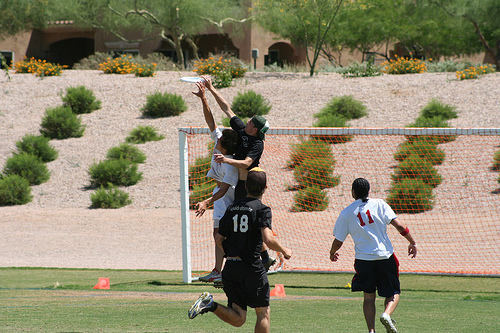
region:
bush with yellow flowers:
[17, 54, 39, 75]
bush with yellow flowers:
[43, 62, 65, 78]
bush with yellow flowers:
[101, 43, 133, 85]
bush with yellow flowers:
[136, 61, 161, 80]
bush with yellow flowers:
[187, 52, 228, 79]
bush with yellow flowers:
[388, 44, 420, 83]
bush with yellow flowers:
[456, 53, 495, 90]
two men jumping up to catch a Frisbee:
[171, 50, 273, 187]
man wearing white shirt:
[339, 195, 412, 258]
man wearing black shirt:
[215, 194, 278, 258]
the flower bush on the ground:
[7, 56, 67, 78]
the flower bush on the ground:
[98, 50, 155, 77]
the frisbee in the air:
[180, 73, 204, 82]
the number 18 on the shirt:
[232, 213, 247, 233]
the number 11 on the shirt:
[355, 209, 375, 225]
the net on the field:
[178, 127, 498, 283]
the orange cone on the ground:
[92, 275, 109, 288]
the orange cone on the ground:
[270, 284, 286, 297]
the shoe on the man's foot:
[188, 290, 213, 317]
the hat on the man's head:
[251, 113, 268, 141]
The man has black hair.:
[349, 175, 371, 204]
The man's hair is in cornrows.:
[346, 175, 375, 199]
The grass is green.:
[72, 309, 107, 331]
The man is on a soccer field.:
[326, 176, 428, 331]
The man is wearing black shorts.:
[345, 256, 407, 297]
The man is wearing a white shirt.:
[326, 196, 407, 261]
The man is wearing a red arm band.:
[398, 223, 412, 238]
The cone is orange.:
[89, 277, 112, 294]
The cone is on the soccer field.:
[88, 276, 112, 292]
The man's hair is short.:
[244, 166, 268, 197]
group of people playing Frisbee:
[174, 66, 419, 331]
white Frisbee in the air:
[175, 70, 221, 90]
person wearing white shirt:
[332, 175, 422, 275]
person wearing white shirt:
[202, 143, 234, 198]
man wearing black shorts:
[335, 180, 410, 311]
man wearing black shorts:
[217, 250, 265, 305]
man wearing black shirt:
[235, 115, 261, 161]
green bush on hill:
[43, 106, 85, 136]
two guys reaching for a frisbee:
[177, 74, 272, 267]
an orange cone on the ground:
[86, 271, 113, 294]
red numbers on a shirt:
[350, 209, 382, 231]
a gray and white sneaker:
[186, 295, 218, 322]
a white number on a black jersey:
[231, 206, 256, 239]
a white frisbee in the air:
[176, 68, 206, 85]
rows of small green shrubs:
[34, 82, 174, 212]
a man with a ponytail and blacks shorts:
[337, 170, 426, 325]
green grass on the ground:
[41, 291, 163, 328]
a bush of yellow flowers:
[374, 47, 429, 78]